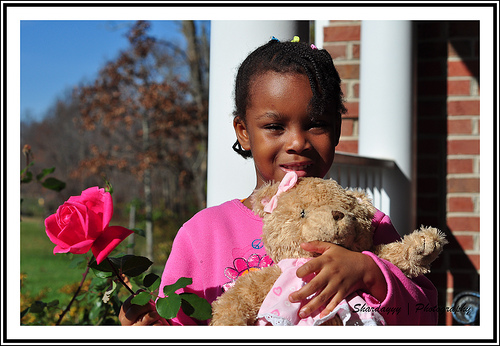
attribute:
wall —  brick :
[319, 22, 481, 324]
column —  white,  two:
[358, 20, 417, 237]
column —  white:
[200, 17, 310, 209]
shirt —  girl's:
[153, 195, 400, 339]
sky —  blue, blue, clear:
[21, 22, 213, 129]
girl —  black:
[162, 46, 429, 314]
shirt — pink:
[142, 188, 440, 324]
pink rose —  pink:
[33, 160, 161, 317]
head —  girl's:
[234, 33, 350, 185]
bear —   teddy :
[245, 167, 409, 325]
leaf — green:
[156, 296, 181, 322]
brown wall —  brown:
[418, 27, 480, 248]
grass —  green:
[28, 265, 78, 303]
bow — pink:
[260, 173, 292, 223]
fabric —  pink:
[254, 256, 389, 324]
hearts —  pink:
[264, 281, 286, 313]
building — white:
[202, 22, 412, 242]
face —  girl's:
[245, 69, 336, 183]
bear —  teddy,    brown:
[213, 170, 445, 326]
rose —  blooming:
[42, 183, 132, 263]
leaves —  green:
[155, 275, 213, 322]